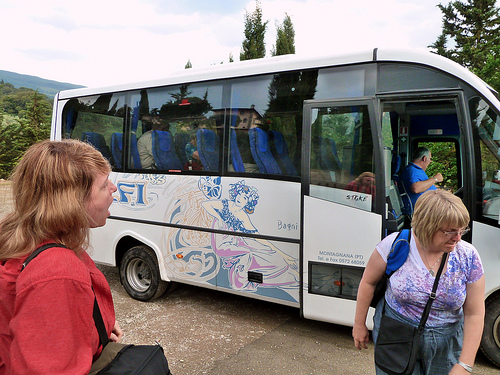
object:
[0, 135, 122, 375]
person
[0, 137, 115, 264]
hair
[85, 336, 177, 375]
bag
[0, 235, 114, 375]
shirt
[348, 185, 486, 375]
woman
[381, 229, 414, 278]
strap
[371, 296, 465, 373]
pants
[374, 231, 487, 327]
shirt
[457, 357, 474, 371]
band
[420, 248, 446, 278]
necklace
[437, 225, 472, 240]
glasses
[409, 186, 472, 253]
hair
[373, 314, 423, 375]
bag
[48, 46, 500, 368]
bus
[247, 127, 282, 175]
seats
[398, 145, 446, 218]
driver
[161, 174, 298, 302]
advertisement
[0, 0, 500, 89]
sky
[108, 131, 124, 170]
seats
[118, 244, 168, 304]
tire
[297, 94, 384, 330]
door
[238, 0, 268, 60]
tree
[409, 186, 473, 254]
head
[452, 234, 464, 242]
nose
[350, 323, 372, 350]
hand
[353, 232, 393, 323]
arm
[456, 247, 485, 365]
arm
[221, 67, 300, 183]
window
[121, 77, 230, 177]
window